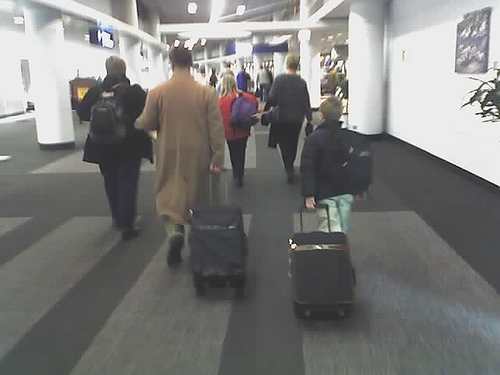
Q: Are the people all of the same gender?
A: No, they are both male and female.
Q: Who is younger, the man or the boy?
A: The boy is younger than the man.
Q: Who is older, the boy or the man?
A: The man is older than the boy.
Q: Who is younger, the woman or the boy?
A: The boy is younger than the woman.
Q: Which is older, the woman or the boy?
A: The woman is older than the boy.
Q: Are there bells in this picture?
A: No, there are no bells.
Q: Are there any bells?
A: No, there are no bells.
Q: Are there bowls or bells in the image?
A: No, there are no bells or bowls.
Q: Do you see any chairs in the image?
A: No, there are no chairs.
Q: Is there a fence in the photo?
A: No, there are no fences.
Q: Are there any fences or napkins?
A: No, there are no fences or napkins.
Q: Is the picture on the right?
A: Yes, the picture is on the right of the image.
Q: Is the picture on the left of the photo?
A: No, the picture is on the right of the image.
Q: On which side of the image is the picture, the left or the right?
A: The picture is on the right of the image.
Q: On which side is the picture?
A: The picture is on the right of the image.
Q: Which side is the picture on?
A: The picture is on the right of the image.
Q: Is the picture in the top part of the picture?
A: Yes, the picture is in the top of the image.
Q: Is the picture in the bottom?
A: No, the picture is in the top of the image.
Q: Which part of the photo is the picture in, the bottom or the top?
A: The picture is in the top of the image.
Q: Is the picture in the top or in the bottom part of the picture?
A: The picture is in the top of the image.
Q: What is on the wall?
A: The picture is on the wall.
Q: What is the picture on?
A: The picture is on the wall.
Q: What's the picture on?
A: The picture is on the wall.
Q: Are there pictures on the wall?
A: Yes, there is a picture on the wall.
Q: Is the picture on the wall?
A: Yes, the picture is on the wall.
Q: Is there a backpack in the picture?
A: Yes, there is a backpack.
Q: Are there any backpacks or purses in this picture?
A: Yes, there is a backpack.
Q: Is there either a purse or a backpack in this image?
A: Yes, there is a backpack.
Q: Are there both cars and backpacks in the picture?
A: No, there is a backpack but no cars.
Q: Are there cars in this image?
A: No, there are no cars.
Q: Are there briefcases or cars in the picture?
A: No, there are no cars or briefcases.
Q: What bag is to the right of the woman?
A: The bag is a backpack.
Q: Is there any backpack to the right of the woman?
A: Yes, there is a backpack to the right of the woman.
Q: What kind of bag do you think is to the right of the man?
A: The bag is a backpack.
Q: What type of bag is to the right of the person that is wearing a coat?
A: The bag is a backpack.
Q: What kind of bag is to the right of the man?
A: The bag is a backpack.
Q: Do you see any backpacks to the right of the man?
A: Yes, there is a backpack to the right of the man.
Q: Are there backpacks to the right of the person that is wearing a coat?
A: Yes, there is a backpack to the right of the man.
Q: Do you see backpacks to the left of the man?
A: No, the backpack is to the right of the man.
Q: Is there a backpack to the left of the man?
A: No, the backpack is to the right of the man.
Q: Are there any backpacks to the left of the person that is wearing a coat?
A: No, the backpack is to the right of the man.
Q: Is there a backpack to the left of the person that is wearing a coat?
A: No, the backpack is to the right of the man.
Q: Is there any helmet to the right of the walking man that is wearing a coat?
A: No, there is a backpack to the right of the man.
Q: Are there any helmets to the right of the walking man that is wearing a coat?
A: No, there is a backpack to the right of the man.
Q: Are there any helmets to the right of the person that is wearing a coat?
A: No, there is a backpack to the right of the man.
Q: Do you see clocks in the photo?
A: No, there are no clocks.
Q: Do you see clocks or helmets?
A: No, there are no clocks or helmets.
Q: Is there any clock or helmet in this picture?
A: No, there are no clocks or helmets.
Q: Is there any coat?
A: Yes, there is a coat.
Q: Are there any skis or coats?
A: Yes, there is a coat.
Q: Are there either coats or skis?
A: Yes, there is a coat.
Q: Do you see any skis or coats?
A: Yes, there is a coat.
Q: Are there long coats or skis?
A: Yes, there is a long coat.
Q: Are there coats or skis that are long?
A: Yes, the coat is long.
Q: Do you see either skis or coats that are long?
A: Yes, the coat is long.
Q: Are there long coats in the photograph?
A: Yes, there is a long coat.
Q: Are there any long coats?
A: Yes, there is a long coat.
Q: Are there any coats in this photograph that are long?
A: Yes, there is a coat that is long.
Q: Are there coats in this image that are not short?
A: Yes, there is a long coat.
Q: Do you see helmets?
A: No, there are no helmets.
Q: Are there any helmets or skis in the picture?
A: No, there are no helmets or skis.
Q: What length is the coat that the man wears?
A: The coat is long.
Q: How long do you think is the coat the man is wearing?
A: The coat is long.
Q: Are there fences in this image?
A: No, there are no fences.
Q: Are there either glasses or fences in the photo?
A: No, there are no fences or glasses.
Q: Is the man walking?
A: Yes, the man is walking.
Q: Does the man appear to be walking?
A: Yes, the man is walking.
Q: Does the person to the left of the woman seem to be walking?
A: Yes, the man is walking.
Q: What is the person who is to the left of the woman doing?
A: The man is walking.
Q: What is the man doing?
A: The man is walking.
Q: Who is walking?
A: The man is walking.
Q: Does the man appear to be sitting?
A: No, the man is walking.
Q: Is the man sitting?
A: No, the man is walking.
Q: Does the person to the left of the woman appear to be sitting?
A: No, the man is walking.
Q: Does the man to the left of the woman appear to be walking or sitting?
A: The man is walking.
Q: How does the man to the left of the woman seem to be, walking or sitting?
A: The man is walking.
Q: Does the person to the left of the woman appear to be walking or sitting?
A: The man is walking.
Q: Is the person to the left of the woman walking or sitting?
A: The man is walking.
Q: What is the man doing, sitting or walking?
A: The man is walking.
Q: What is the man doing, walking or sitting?
A: The man is walking.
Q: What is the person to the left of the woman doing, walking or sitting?
A: The man is walking.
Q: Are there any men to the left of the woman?
A: Yes, there is a man to the left of the woman.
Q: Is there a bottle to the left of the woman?
A: No, there is a man to the left of the woman.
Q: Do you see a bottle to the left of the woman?
A: No, there is a man to the left of the woman.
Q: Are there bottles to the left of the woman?
A: No, there is a man to the left of the woman.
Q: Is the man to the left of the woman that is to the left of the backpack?
A: Yes, the man is to the left of the woman.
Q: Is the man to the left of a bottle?
A: No, the man is to the left of the woman.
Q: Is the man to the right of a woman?
A: No, the man is to the left of a woman.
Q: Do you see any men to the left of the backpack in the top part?
A: Yes, there is a man to the left of the backpack.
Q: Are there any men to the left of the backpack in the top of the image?
A: Yes, there is a man to the left of the backpack.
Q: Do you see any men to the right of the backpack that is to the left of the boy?
A: No, the man is to the left of the backpack.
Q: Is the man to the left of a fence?
A: No, the man is to the left of the backpack.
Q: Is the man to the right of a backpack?
A: No, the man is to the left of a backpack.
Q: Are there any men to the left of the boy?
A: Yes, there is a man to the left of the boy.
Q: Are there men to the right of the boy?
A: No, the man is to the left of the boy.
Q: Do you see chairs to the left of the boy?
A: No, there is a man to the left of the boy.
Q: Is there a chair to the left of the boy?
A: No, there is a man to the left of the boy.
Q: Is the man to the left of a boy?
A: Yes, the man is to the left of a boy.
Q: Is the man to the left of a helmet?
A: No, the man is to the left of a boy.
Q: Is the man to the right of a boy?
A: No, the man is to the left of a boy.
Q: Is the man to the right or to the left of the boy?
A: The man is to the left of the boy.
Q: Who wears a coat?
A: The man wears a coat.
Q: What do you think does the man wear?
A: The man wears a coat.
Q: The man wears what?
A: The man wears a coat.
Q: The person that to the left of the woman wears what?
A: The man wears a coat.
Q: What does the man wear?
A: The man wears a coat.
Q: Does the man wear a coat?
A: Yes, the man wears a coat.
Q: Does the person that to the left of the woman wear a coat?
A: Yes, the man wears a coat.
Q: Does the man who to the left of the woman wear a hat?
A: No, the man wears a coat.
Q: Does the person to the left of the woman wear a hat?
A: No, the man wears a coat.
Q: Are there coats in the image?
A: Yes, there is a coat.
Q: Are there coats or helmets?
A: Yes, there is a coat.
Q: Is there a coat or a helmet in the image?
A: Yes, there is a coat.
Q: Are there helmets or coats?
A: Yes, there is a coat.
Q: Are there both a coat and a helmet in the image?
A: No, there is a coat but no helmets.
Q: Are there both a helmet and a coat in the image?
A: No, there is a coat but no helmets.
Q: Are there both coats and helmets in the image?
A: No, there is a coat but no helmets.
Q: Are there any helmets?
A: No, there are no helmets.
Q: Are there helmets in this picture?
A: No, there are no helmets.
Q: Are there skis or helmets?
A: No, there are no helmets or skis.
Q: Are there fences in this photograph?
A: No, there are no fences.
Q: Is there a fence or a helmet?
A: No, there are no fences or helmets.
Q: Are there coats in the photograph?
A: Yes, there is a coat.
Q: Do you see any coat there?
A: Yes, there is a coat.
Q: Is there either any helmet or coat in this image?
A: Yes, there is a coat.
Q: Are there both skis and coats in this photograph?
A: No, there is a coat but no skis.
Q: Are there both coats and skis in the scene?
A: No, there is a coat but no skis.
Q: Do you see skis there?
A: No, there are no skis.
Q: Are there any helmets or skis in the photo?
A: No, there are no skis or helmets.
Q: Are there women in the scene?
A: Yes, there is a woman.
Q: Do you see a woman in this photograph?
A: Yes, there is a woman.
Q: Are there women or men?
A: Yes, there is a woman.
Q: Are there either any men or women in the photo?
A: Yes, there is a woman.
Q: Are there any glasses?
A: No, there are no glasses.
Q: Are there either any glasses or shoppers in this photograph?
A: No, there are no glasses or shoppers.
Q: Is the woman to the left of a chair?
A: No, the woman is to the left of the backpack.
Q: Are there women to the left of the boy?
A: Yes, there is a woman to the left of the boy.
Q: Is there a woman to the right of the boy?
A: No, the woman is to the left of the boy.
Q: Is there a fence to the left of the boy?
A: No, there is a woman to the left of the boy.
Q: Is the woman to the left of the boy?
A: Yes, the woman is to the left of the boy.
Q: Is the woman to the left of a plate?
A: No, the woman is to the left of the boy.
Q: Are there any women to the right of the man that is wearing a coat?
A: Yes, there is a woman to the right of the man.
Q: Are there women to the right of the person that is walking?
A: Yes, there is a woman to the right of the man.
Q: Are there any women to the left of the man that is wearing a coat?
A: No, the woman is to the right of the man.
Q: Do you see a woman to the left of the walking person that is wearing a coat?
A: No, the woman is to the right of the man.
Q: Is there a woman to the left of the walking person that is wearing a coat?
A: No, the woman is to the right of the man.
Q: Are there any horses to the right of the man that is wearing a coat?
A: No, there is a woman to the right of the man.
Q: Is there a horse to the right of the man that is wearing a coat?
A: No, there is a woman to the right of the man.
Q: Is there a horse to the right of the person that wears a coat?
A: No, there is a woman to the right of the man.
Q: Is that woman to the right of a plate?
A: No, the woman is to the right of the man.